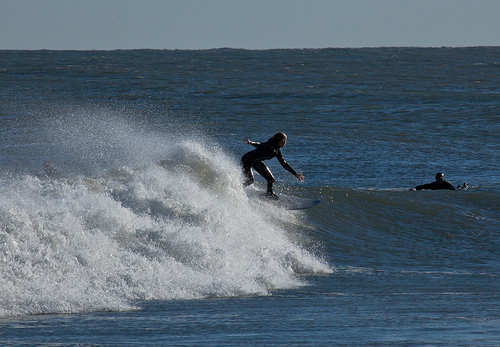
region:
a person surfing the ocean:
[172, 121, 322, 216]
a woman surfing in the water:
[204, 97, 305, 262]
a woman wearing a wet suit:
[231, 121, 305, 202]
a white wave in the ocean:
[42, 196, 314, 274]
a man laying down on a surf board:
[411, 160, 481, 201]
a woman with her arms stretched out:
[243, 125, 312, 195]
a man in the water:
[400, 150, 471, 215]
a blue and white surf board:
[259, 190, 324, 229]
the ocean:
[12, 36, 473, 127]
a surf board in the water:
[235, 180, 327, 245]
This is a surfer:
[215, 106, 358, 218]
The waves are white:
[197, 191, 326, 324]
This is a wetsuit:
[196, 125, 296, 247]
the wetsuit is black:
[189, 104, 351, 304]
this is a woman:
[185, 95, 360, 305]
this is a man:
[372, 160, 482, 207]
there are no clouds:
[320, 10, 351, 50]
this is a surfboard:
[240, 180, 365, 250]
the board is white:
[211, 142, 344, 281]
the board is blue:
[254, 150, 262, 167]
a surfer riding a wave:
[217, 125, 347, 246]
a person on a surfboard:
[233, 121, 327, 216]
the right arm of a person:
[280, 155, 297, 178]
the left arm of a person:
[252, 135, 259, 145]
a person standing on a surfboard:
[233, 162, 280, 209]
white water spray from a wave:
[42, 90, 162, 157]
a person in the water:
[410, 156, 474, 216]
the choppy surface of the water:
[335, 92, 381, 134]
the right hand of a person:
[298, 169, 308, 183]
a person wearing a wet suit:
[217, 116, 306, 222]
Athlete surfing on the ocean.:
[240, 130, 320, 210]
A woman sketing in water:
[215, 100, 355, 231]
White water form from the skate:
[160, 133, 272, 293]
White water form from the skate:
[21, 161, 142, 293]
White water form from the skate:
[34, 100, 149, 157]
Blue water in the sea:
[332, 260, 456, 345]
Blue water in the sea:
[350, 75, 452, 140]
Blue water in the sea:
[212, 51, 334, 121]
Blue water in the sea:
[408, 44, 492, 118]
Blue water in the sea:
[94, 41, 228, 85]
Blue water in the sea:
[12, 50, 89, 102]